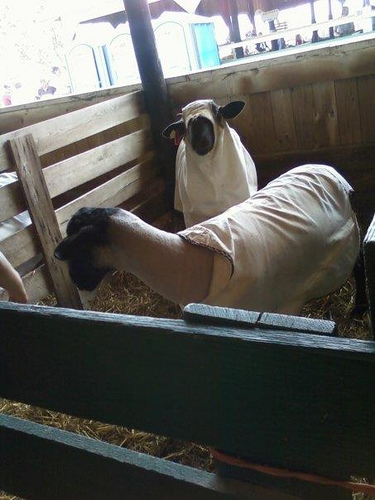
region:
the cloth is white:
[168, 94, 264, 231]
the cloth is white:
[181, 171, 374, 362]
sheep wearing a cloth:
[31, 166, 369, 354]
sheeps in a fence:
[49, 35, 373, 341]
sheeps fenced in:
[56, 37, 374, 417]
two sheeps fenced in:
[41, 51, 370, 415]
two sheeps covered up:
[30, 52, 312, 394]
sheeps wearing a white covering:
[82, 74, 320, 376]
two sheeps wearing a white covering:
[81, 89, 374, 303]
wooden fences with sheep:
[42, 44, 372, 446]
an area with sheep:
[32, 51, 374, 392]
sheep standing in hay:
[61, 111, 337, 427]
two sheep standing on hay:
[22, 23, 364, 396]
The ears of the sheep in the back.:
[155, 97, 246, 137]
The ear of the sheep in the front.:
[43, 227, 103, 259]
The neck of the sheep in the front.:
[124, 218, 201, 306]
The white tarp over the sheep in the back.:
[174, 96, 256, 210]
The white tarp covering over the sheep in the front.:
[185, 165, 373, 308]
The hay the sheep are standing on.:
[2, 229, 374, 496]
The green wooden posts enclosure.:
[3, 301, 364, 497]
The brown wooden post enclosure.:
[14, 50, 370, 305]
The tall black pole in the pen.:
[124, 0, 186, 196]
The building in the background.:
[45, 3, 374, 40]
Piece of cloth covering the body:
[252, 226, 309, 266]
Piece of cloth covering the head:
[191, 108, 207, 112]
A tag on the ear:
[177, 133, 179, 138]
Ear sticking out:
[227, 106, 239, 110]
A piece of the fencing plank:
[54, 120, 100, 129]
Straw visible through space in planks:
[98, 429, 122, 437]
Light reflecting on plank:
[93, 444, 106, 450]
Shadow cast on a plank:
[267, 160, 291, 166]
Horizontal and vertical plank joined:
[263, 321, 293, 333]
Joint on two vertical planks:
[256, 314, 262, 319]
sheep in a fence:
[49, 51, 361, 322]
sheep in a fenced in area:
[62, 28, 353, 364]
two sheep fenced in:
[84, 52, 337, 370]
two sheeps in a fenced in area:
[64, 62, 370, 458]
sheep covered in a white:
[27, 73, 342, 310]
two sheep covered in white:
[57, 41, 359, 364]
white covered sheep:
[92, 87, 362, 365]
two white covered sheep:
[88, 80, 355, 337]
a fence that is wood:
[6, 52, 370, 401]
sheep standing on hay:
[46, 108, 364, 386]